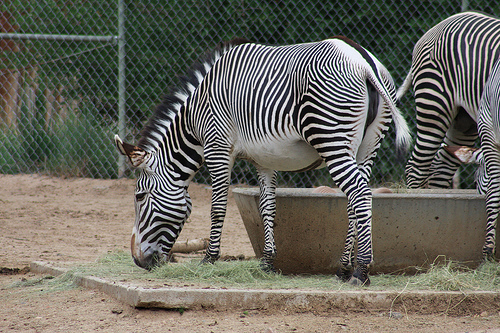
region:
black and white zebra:
[86, 16, 391, 269]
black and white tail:
[352, 41, 429, 178]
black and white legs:
[192, 170, 377, 273]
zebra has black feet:
[283, 251, 400, 288]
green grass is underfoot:
[136, 259, 391, 286]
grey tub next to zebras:
[275, 164, 475, 263]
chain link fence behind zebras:
[15, 10, 242, 143]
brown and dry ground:
[24, 191, 107, 259]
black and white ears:
[99, 144, 154, 178]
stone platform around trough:
[55, 253, 494, 315]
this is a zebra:
[115, 29, 420, 294]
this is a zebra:
[404, 23, 499, 247]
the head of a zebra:
[106, 127, 193, 284]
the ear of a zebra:
[108, 124, 160, 177]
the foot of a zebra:
[183, 131, 240, 281]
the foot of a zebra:
[248, 164, 294, 279]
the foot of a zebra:
[328, 137, 376, 298]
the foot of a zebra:
[337, 140, 382, 277]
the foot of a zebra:
[405, 81, 439, 193]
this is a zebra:
[114, 33, 407, 298]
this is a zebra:
[393, 5, 498, 266]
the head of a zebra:
[108, 168, 194, 279]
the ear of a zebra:
[108, 124, 153, 169]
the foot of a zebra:
[240, 158, 288, 273]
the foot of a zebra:
[326, 132, 383, 297]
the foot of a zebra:
[333, 162, 384, 275]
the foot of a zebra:
[401, 73, 444, 190]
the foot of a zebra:
[471, 145, 498, 266]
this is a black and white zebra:
[105, 41, 410, 287]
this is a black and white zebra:
[388, 22, 493, 253]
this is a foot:
[195, 148, 240, 283]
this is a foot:
[470, 137, 496, 254]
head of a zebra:
[90, 127, 200, 289]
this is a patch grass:
[167, 251, 272, 293]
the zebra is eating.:
[122, 40, 407, 281]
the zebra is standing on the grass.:
[125, 26, 400, 281]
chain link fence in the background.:
[1, 0, 496, 167]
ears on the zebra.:
[110, 131, 150, 166]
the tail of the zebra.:
[371, 55, 411, 145]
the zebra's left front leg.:
[200, 131, 235, 263]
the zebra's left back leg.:
[305, 76, 370, 281]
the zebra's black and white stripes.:
[466, 10, 481, 120]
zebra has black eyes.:
[132, 186, 142, 201]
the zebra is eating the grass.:
[121, 28, 403, 297]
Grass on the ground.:
[127, 243, 345, 308]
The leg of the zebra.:
[203, 159, 240, 271]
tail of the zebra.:
[366, 72, 422, 143]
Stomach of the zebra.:
[233, 133, 318, 183]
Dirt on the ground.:
[16, 178, 131, 268]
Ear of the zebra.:
[107, 128, 169, 182]